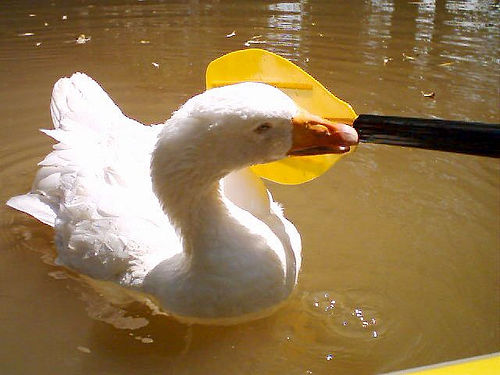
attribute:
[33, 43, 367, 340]
duck — white , swimming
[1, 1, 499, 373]
water — body, murky, calm , murky water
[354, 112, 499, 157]
pole — black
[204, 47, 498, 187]
paddle — black , yellow 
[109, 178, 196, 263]
feathers — white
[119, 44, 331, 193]
head — yellow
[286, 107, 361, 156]
beak — orange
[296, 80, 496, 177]
pole — black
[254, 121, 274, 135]
eye — round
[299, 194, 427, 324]
water — brown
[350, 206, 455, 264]
water — murky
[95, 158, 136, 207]
feathers — white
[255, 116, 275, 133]
eye — small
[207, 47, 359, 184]
paddle — yellow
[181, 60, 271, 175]
duck — white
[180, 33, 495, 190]
paddle — black, stick 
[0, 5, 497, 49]
water — body 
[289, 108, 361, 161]
beak — open